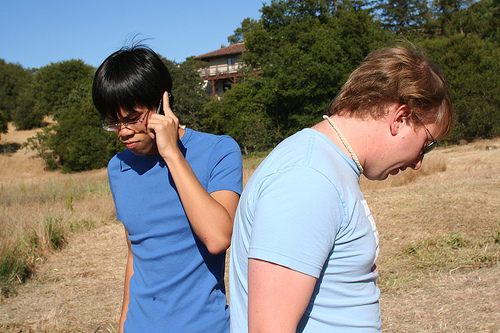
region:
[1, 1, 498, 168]
The bushes in the distance.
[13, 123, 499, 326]
The dried up grass in the area.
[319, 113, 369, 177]
The white necklace the boy on the right is wearing.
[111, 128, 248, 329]
The blue shirt the boy on the left is wearing.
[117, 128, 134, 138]
The nose of the guy on the left.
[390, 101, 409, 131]
The ear of the guy on the right.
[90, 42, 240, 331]
boy holding phone to head with hand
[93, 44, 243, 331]
black haired boy in blue shirt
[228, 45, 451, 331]
side view of person wearing eyeglasses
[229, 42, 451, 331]
person wearing white necklace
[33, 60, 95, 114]
green leaves on tree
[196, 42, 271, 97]
exterior of house with deck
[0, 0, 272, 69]
clear blue daytime sky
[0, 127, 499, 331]
dried brown grass on ground surface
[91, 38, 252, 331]
this is a person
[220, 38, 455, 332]
this is a person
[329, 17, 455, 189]
this is a person's head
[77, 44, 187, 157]
this is a person's head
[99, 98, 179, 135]
this is a pair of glasses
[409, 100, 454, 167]
this is a person's glasses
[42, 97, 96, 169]
this is green vegetation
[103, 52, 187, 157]
a boy holding a cell phone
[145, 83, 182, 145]
a boy using a cell phone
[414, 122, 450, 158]
a boy wearing glasses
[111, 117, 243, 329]
a boy wearing a blue shirt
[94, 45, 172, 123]
a boy with black hair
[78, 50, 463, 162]
two boys wearing glasses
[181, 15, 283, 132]
a house surrounded by trees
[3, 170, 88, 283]
tall brown grass in a field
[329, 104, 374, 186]
a boy wearing a white necklace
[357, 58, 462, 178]
a boy looking down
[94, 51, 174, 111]
The black hair of the boy.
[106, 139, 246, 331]
The darker blue shirt the boy is wearing.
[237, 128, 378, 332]
The light blue shirt the guy is wearing.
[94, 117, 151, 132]
The eyeglasses the boy on the left is wearing.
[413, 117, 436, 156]
The eyeglasses the guy on the right is wearing.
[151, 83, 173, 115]
The phone the boy is using.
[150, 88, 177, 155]
The guy's hand on the cell phone.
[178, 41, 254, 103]
The house in the background.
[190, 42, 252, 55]
The brown roof of the house.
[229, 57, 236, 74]
The door on the second floor of the house.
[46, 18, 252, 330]
man in blue talking on his cell phone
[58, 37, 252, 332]
asian man in blue talking on his cell phone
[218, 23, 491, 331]
man in light blue shirt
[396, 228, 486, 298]
grass growing on a hillside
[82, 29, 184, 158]
the mans head above shoulders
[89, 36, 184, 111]
the hair on the mans head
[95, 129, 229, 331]
the mans shirt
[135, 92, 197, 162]
the mans hand at end of arm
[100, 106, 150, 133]
man wearing wire rimmed glasses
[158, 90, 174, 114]
man holding cell phone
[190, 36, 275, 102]
house behind two men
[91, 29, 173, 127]
man with short black hair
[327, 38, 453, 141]
man with blonde hair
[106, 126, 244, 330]
man wearing light blue shirt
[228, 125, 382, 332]
man wearing light green shirt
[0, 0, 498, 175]
green trees behind man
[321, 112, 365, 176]
white necklace around neck